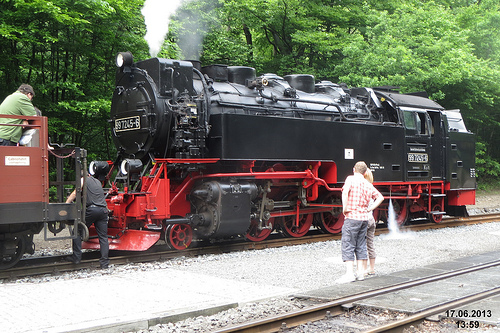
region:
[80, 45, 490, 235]
red and black train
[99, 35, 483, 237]
train stopped on tracks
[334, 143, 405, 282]
couple standing together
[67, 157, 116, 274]
man checking out train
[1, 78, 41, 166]
man wearing light green shirt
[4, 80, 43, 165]
man wearing baseball hat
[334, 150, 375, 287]
man wearing checkered shirt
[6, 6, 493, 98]
forest in the background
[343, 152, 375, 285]
man wearing short pants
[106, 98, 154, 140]
numbers on back of train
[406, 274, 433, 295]
part of a rail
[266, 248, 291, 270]
part of a ground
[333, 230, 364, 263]
part of a short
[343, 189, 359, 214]
part of a shirt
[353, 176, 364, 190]
part of a shirt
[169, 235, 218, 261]
wheel of a train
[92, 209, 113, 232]
part of a trouser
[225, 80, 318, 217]
side of a train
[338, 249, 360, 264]
edge of a short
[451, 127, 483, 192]
edge of a train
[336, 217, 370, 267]
man wearing gray pants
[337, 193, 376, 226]
man with hands on hips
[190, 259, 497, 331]
empty train tracks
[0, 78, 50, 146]
man is sitting on train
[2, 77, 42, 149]
man is wearing a green shirt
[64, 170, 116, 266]
man is wearing a black shirt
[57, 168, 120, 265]
man is wearing black pants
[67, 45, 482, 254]
the train engine is black and red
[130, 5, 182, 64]
steam coming out of train engine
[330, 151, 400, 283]
People standing by a train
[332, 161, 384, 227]
Man in a plaid shirt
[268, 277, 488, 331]
Train tracks on the ground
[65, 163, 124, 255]
Man in black by a train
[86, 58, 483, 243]
Black train engine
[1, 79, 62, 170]
Man in a green shirt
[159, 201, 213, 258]
Wheel on a train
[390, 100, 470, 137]
Window on a train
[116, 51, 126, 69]
Light on a train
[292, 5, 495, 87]
Green leaves on a tree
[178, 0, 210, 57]
steam being released from a train engine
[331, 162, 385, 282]
two people talking to each other standing near train tracks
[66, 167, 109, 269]
a man dressed in all black looking at a train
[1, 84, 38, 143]
a man in a green shirt slightly leaned over railing, looking down at the man dressed in black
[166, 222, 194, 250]
red wheel on a train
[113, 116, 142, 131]
numbers found at the end of a train car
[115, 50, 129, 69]
light on the top of the train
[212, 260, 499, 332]
train tracks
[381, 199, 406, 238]
steam being released into the atmosphere from a train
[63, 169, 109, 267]
a man inspecting a train